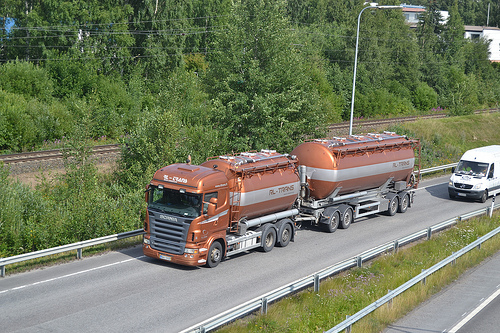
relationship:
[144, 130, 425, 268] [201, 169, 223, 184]
truck colored copper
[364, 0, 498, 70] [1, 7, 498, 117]
house in trees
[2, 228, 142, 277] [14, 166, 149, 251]
guardrail on side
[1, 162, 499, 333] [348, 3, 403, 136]
freeway by a street light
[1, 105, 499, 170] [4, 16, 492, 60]
tracks below lines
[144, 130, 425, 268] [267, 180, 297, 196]
truck has writing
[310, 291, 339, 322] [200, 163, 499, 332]
grass between road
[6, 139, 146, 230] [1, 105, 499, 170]
trees in front of tracks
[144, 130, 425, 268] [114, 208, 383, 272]
truck has a shadow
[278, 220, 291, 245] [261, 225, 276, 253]
wheel by another wheel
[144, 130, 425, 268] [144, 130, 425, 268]
truck hauls a truck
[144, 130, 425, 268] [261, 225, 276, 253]
truck has a wheel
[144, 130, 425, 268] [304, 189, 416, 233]
truck has wheels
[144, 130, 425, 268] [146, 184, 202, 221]
truck has a windshield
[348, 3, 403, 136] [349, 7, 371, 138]
lamp on pole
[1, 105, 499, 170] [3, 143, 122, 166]
tracks for train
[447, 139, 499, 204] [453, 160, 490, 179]
mini van has a windshield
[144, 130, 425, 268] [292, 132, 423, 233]
truck has a rig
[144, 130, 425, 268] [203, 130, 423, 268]
truck has two rigs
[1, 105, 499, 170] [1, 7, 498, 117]
tracks between trees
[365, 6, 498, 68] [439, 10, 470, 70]
building behind tree